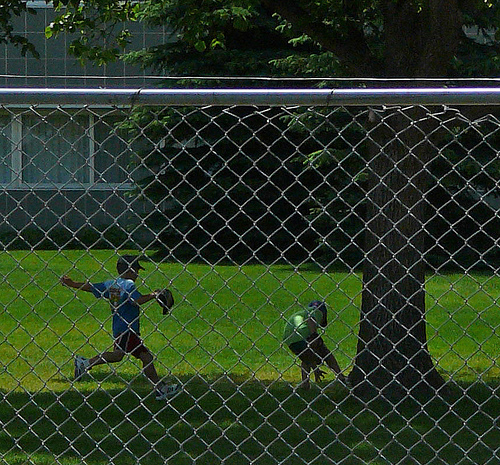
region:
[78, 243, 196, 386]
a kid playing baseball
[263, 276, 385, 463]
a kid bending over for a baseball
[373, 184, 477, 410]
a tree stump in the yard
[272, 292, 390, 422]
boy in green shirt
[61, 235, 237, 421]
boy in blue shirt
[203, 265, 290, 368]
green grass in field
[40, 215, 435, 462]
boys playing baseball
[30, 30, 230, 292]
house in background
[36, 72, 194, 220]
window of house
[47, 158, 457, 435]
chain linked fence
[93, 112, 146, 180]
a window on a building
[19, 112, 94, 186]
a window on a building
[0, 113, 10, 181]
a window on a building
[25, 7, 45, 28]
a window on a building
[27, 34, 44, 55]
a window on a building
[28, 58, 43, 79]
a window on a building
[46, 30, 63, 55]
a window on a building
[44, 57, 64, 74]
a window on a building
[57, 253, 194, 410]
a boy playing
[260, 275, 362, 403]
a boy playing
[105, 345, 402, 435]
large shadow on the grass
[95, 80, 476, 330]
large chain link fence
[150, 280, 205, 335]
mittens in boy's hand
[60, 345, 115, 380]
blue sneakers on boy's feet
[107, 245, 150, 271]
black cap on boy's head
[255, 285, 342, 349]
green shirt on boy's back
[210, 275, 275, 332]
lush manicured green grass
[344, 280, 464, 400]
large stump on tree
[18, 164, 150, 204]
white window ledge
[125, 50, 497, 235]
flowering green leaves on trees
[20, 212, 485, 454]
A chain link fence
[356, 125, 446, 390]
A tree trunk behind the fence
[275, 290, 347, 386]
A little boy in a blue hat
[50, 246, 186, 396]
A little boy throwing a ball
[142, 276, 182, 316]
A mitt on a boy's hand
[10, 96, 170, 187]
A window in a house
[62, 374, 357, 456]
The shadow of a tree on the grass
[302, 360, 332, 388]
A little boy's hand reaching to grab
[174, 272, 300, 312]
A green lawn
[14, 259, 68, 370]
Sun shining on the grass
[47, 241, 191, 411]
Boy is playing on yard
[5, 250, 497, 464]
Yard is cover with green grass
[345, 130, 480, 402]
Trunk of tree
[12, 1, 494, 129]
Canopy of tree is green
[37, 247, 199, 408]
Boy has extended arms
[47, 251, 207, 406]
Boy is running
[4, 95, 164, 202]
Window of home has white frame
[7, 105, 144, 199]
Window has curtain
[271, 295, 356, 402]
Boy next to tree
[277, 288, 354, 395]
Boy has green shirt